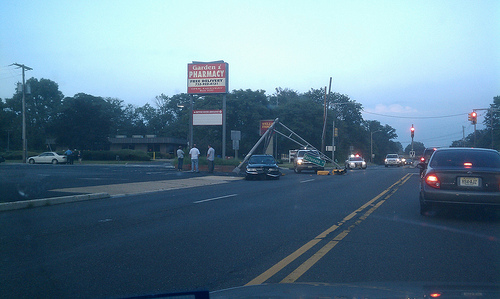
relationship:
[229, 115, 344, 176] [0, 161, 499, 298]
sign that has fallen into highway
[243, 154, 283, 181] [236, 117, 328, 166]
car that hit post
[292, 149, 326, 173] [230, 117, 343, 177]
car behind street sign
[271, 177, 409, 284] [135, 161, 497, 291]
lines painted on highway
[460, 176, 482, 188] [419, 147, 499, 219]
license plate of car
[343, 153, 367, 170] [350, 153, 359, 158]
car with lights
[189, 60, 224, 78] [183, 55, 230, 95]
white text on red sign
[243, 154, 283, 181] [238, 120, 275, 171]
car hit pole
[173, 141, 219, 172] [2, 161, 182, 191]
men standing in parking lot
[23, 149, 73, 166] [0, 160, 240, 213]
car in parking lot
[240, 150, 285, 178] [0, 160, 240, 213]
car in parking lot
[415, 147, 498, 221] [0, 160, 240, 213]
car in parking lot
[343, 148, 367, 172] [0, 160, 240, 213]
car in parking lot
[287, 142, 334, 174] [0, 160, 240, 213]
car in parking lot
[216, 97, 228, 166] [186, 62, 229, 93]
pole elevating red sign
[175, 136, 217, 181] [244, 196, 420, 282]
men standing on surface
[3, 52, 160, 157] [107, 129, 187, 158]
trees behind building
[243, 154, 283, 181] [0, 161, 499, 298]
car on a highway